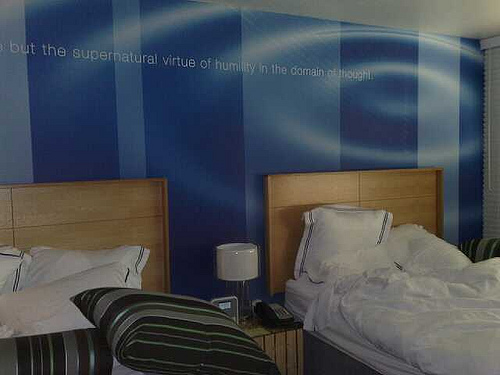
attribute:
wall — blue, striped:
[0, 3, 483, 313]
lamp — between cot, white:
[215, 240, 259, 320]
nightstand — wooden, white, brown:
[238, 308, 303, 374]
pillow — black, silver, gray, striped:
[69, 285, 278, 373]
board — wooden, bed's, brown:
[264, 164, 443, 301]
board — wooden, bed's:
[0, 176, 170, 293]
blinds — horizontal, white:
[479, 35, 499, 240]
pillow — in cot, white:
[385, 219, 473, 280]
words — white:
[8, 37, 372, 81]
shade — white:
[214, 242, 259, 281]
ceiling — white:
[220, 0, 498, 41]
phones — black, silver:
[252, 301, 293, 330]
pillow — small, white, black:
[293, 205, 391, 281]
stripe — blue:
[24, 3, 120, 187]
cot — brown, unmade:
[303, 331, 381, 374]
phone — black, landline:
[249, 299, 294, 328]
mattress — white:
[283, 277, 322, 323]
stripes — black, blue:
[0, 284, 279, 374]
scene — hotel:
[0, 2, 498, 374]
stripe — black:
[112, 311, 253, 358]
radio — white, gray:
[209, 295, 240, 324]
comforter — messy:
[309, 268, 499, 374]